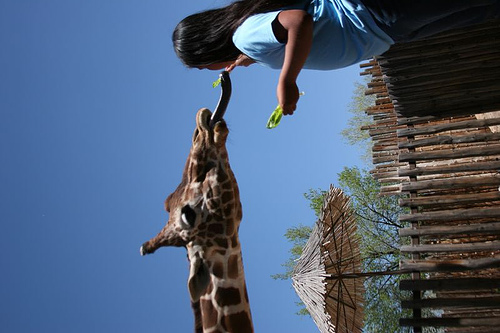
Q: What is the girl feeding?
A: A giraffe.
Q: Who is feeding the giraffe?
A: A girl.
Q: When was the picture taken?
A: Daytime.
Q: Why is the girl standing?
A: Feeding the giraffe.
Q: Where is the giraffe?
A: Behind the fence.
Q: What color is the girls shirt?
A: Blue.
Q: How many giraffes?
A: 1.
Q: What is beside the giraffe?
A: An umbrella.